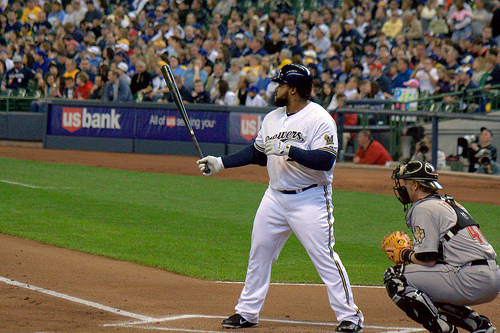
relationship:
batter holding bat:
[196, 63, 365, 333] [161, 64, 211, 171]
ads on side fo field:
[35, 92, 450, 197] [11, 148, 346, 331]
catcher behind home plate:
[382, 160, 500, 332] [103, 312, 462, 331]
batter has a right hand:
[196, 63, 365, 333] [194, 152, 222, 176]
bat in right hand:
[125, 36, 230, 194] [194, 152, 222, 176]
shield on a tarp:
[60, 106, 79, 131] [44, 100, 279, 144]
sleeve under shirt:
[288, 144, 335, 172] [252, 99, 338, 192]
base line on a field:
[0, 276, 154, 322] [2, 139, 498, 329]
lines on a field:
[100, 320, 194, 329] [2, 139, 498, 329]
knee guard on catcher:
[382, 266, 403, 299] [381, 163, 493, 331]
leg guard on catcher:
[390, 287, 456, 331] [381, 163, 493, 331]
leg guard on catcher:
[430, 299, 490, 329] [381, 163, 493, 331]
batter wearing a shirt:
[222, 61, 362, 322] [253, 101, 338, 182]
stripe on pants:
[317, 181, 356, 319] [231, 181, 368, 328]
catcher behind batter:
[377, 157, 499, 332] [157, 61, 366, 331]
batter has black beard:
[196, 63, 365, 333] [273, 91, 290, 106]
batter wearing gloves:
[196, 63, 365, 333] [193, 134, 290, 176]